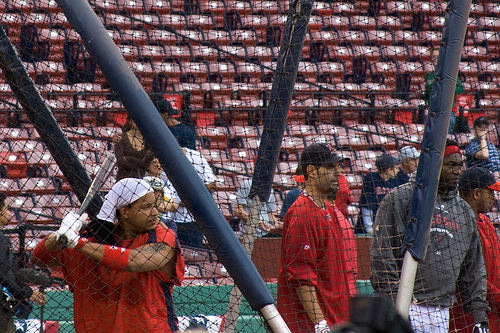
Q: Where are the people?
A: Stadium.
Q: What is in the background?
A: Seats.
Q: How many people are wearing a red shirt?
A: Three.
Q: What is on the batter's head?
A: Dorag.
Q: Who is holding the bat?
A: Man with the dorag.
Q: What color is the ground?
A: Green.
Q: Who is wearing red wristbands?
A: Batter.